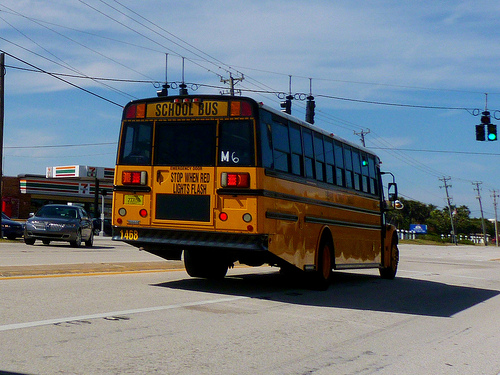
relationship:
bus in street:
[95, 103, 405, 292] [1, 231, 484, 371]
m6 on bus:
[219, 149, 240, 164] [101, 93, 411, 288]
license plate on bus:
[122, 192, 144, 206] [101, 93, 411, 288]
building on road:
[4, 164, 113, 232] [1, 236, 484, 370]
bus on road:
[107, 92, 401, 280] [1, 236, 484, 370]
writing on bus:
[168, 170, 211, 195] [101, 93, 411, 288]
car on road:
[17, 192, 102, 258] [1, 236, 484, 370]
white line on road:
[15, 297, 193, 329] [35, 277, 482, 365]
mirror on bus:
[389, 183, 398, 204] [101, 93, 411, 288]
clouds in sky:
[2, 37, 201, 87] [0, 0, 497, 221]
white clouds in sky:
[0, 0, 497, 97] [0, 0, 497, 221]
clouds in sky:
[0, 0, 497, 99] [0, 0, 497, 221]